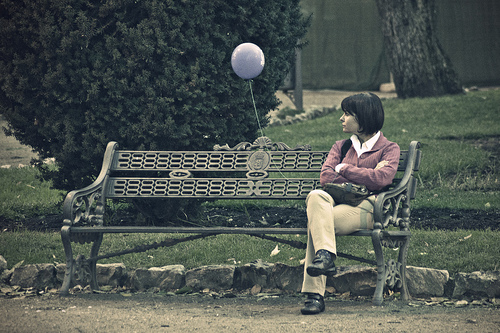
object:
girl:
[300, 90, 402, 314]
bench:
[55, 136, 421, 305]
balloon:
[230, 41, 266, 80]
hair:
[340, 91, 385, 135]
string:
[248, 80, 301, 187]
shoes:
[300, 292, 326, 314]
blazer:
[319, 130, 401, 189]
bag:
[321, 181, 371, 207]